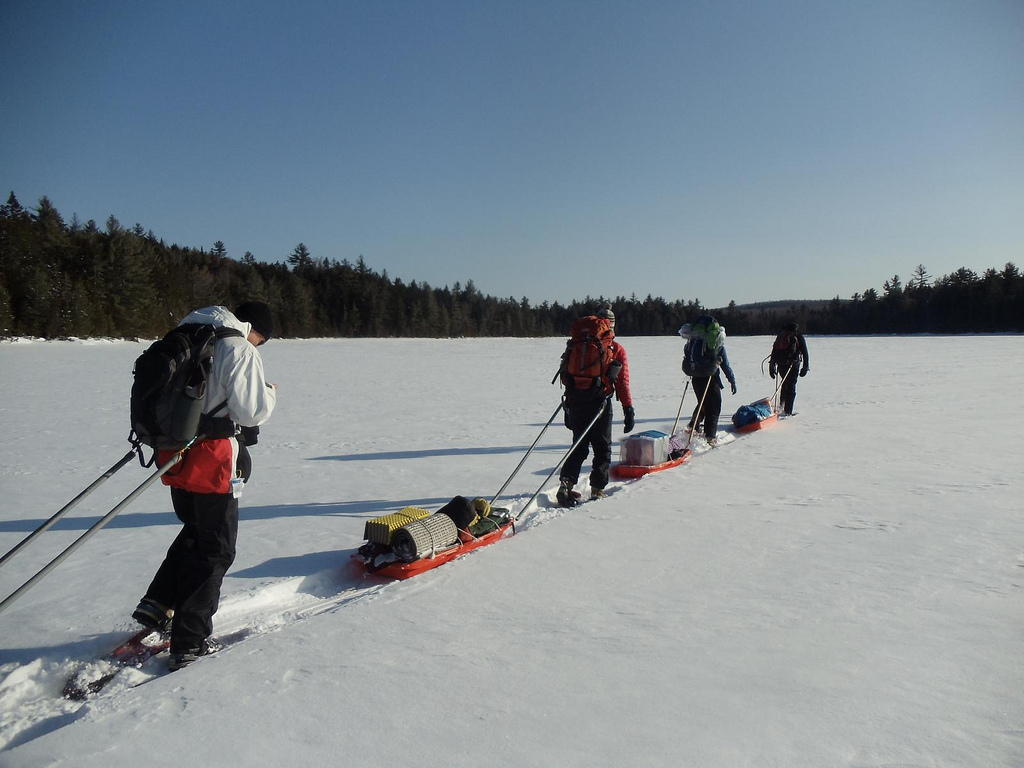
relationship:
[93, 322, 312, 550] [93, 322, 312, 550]
man wearing jacket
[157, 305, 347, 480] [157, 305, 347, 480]
arm of man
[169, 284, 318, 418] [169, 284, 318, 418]
hood of man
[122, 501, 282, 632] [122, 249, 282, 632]
leg of man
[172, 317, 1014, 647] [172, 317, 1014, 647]
people walking on snow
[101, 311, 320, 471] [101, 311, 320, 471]
backpack on person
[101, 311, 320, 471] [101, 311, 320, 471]
person wearing shirt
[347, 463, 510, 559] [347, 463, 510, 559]
package on cart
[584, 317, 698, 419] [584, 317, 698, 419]
backpack on person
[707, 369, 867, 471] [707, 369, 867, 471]
bag on surface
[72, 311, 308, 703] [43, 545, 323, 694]
person wearing skis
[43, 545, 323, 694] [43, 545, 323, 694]
skis on feet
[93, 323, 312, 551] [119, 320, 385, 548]
man has jacket